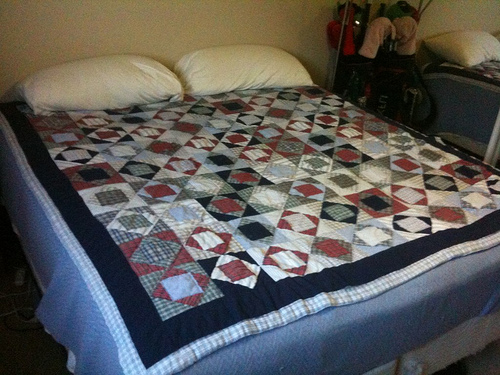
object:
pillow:
[422, 28, 499, 67]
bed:
[421, 54, 499, 84]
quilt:
[0, 85, 499, 374]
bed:
[0, 80, 499, 375]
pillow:
[11, 54, 185, 119]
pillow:
[171, 43, 316, 98]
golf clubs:
[323, 0, 350, 90]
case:
[13, 52, 185, 118]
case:
[170, 41, 320, 97]